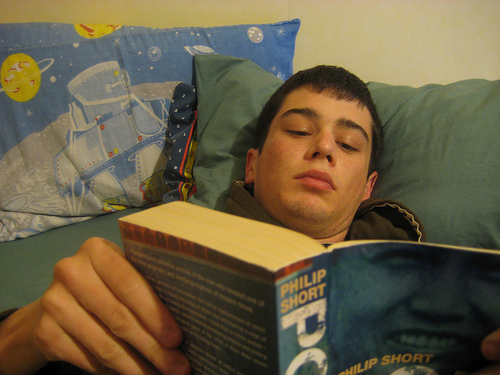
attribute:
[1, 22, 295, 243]
pillow — themed, blue, stamped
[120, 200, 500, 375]
book — thick, blue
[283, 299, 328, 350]
letter — bold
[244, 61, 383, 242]
man — young, reading, lying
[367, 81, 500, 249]
pillow — green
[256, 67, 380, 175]
hair — brown, short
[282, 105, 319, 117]
eyebrow — black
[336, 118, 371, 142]
eyebrow — black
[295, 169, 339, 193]
lips — pink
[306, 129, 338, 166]
nose — big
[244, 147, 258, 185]
ear — small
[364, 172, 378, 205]
ear — small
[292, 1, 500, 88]
wall — beige